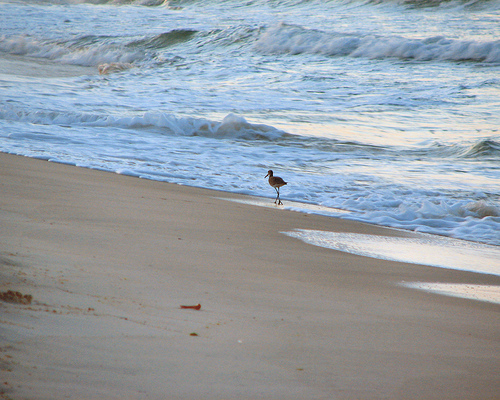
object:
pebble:
[190, 333, 198, 336]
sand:
[2, 281, 498, 397]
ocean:
[1, 1, 493, 256]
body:
[268, 176, 288, 187]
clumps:
[3, 289, 31, 305]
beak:
[264, 174, 269, 178]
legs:
[275, 187, 280, 202]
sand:
[339, 236, 394, 252]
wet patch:
[252, 197, 332, 211]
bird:
[264, 170, 288, 205]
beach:
[5, 145, 497, 398]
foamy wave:
[5, 9, 495, 156]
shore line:
[0, 149, 498, 246]